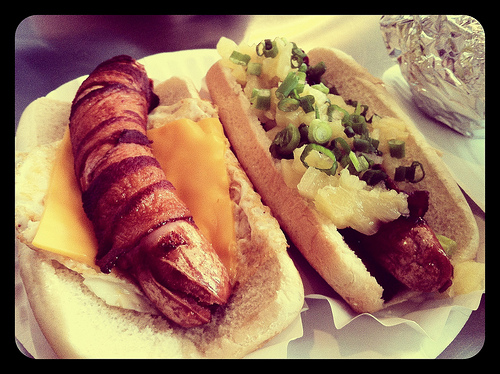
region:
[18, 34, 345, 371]
bacon wrapped sausage on bun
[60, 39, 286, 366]
bacon wrapped sausage on cheese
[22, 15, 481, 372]
two hot dogs on paper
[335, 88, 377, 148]
green onion slice on hot dog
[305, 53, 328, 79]
green onion slice on hot dog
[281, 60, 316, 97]
green onion slice on hot dog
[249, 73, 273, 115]
green onion slice on hot dog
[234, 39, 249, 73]
green onion slice on hot dog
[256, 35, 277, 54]
green onion slice on hot dog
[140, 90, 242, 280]
yellow cheese under sausage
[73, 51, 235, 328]
bacon rolled on a sausage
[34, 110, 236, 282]
a slice of orange cheese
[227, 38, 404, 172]
chopped green onions on a hot dog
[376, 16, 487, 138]
a ball of aluminum paper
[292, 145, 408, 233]
white chopped white onions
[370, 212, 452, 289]
tip of a sausage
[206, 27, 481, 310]
a hot dog with chopped white onions and green onions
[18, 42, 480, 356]
two hot dogs on a white plate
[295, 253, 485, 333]
a paper doily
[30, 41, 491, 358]
a plate with two hotdogs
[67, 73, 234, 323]
a hot dog wrapped in bacon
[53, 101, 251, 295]
a piece of cheese under hot dog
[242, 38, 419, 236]
onions on top of hot dog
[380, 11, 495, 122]
a wad of tin foil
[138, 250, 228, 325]
a split on the hot dog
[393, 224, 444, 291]
ketchup on the hot dog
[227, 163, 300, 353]
the hot dog bun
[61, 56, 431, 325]
two grilled hot dogs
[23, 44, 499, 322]
hot dogs on plate ready to eat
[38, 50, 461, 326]
these are hot dogs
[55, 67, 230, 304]
the hot dog is wrapped in bacon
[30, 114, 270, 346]
there is cheese on the hot dog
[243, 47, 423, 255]
there are green onions on the hot dog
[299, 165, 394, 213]
the relish is yellow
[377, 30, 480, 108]
this is aluminum foil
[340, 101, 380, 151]
green onion slice on hot dog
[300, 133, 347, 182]
green onion slice on hot dog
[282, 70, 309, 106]
green onion slice on hot dog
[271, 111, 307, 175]
green onion slice on hot dog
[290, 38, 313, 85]
green onion slice on hot dog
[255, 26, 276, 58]
green onion slice on hot dog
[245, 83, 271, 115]
green onion slice on hot dog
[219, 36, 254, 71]
green onion slice on hot dog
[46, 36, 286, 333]
bacon wrapped sausage on cheese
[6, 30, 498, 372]
two hot dogs on paper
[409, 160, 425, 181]
chive is on a hot dog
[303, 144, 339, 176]
chive is on a hot dog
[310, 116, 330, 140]
chive is on a hot dog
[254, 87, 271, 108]
chive is on a hot dog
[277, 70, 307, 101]
chive is on a hot dog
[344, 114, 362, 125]
chive is on a hot dog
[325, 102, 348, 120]
chive is on a hot dog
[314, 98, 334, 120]
chive is on a hot dog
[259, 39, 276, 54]
chive is on a hot dog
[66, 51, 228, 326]
hot dog wrapped in bacon